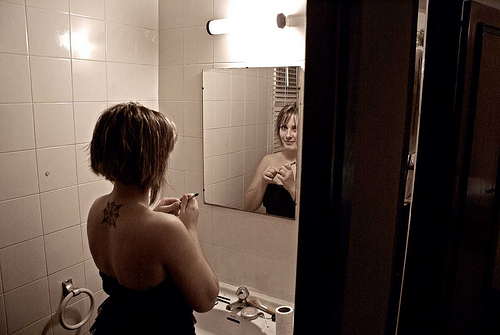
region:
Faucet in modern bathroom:
[224, 284, 261, 324]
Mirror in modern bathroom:
[209, 78, 247, 128]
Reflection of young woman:
[243, 107, 301, 213]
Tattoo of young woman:
[99, 197, 126, 234]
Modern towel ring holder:
[52, 279, 97, 331]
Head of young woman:
[89, 103, 179, 193]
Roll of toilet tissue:
[276, 302, 292, 334]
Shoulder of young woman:
[143, 224, 184, 268]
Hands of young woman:
[153, 188, 207, 219]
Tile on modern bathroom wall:
[16, 81, 76, 174]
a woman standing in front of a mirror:
[96, 62, 301, 277]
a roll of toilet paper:
[273, 293, 295, 334]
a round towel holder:
[48, 268, 105, 334]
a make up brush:
[250, 287, 275, 318]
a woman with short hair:
[101, 94, 189, 190]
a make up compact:
[237, 302, 262, 327]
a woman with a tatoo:
[97, 173, 146, 250]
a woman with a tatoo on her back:
[86, 189, 143, 251]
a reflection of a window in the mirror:
[251, 62, 300, 152]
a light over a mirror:
[200, 4, 295, 51]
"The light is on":
[181, 2, 321, 58]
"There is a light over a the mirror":
[192, 7, 305, 220]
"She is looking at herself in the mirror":
[65, 49, 310, 333]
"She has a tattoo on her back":
[81, 88, 217, 331]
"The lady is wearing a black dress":
[82, 95, 236, 332]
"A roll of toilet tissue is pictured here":
[270, 300, 298, 333]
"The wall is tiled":
[0, 0, 206, 327]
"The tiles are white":
[0, 2, 188, 328]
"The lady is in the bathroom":
[1, 0, 498, 332]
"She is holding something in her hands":
[82, 95, 228, 305]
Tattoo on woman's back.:
[97, 197, 125, 230]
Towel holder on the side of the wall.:
[53, 275, 96, 332]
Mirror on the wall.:
[198, 70, 300, 222]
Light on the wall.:
[195, 9, 295, 36]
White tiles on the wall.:
[3, 2, 102, 326]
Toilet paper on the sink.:
[268, 303, 295, 333]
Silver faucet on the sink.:
[222, 285, 248, 322]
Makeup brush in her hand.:
[173, 192, 204, 210]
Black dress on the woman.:
[81, 105, 215, 333]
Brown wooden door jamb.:
[334, 43, 411, 334]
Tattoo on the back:
[81, 198, 131, 239]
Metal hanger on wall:
[37, 275, 96, 333]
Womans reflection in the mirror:
[237, 98, 309, 234]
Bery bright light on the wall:
[200, 11, 297, 50]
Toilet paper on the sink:
[265, 301, 295, 333]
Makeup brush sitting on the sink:
[241, 285, 282, 321]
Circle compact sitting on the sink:
[236, 303, 261, 326]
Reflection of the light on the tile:
[45, 9, 105, 66]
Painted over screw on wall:
[22, 161, 62, 192]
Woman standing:
[55, 63, 210, 317]